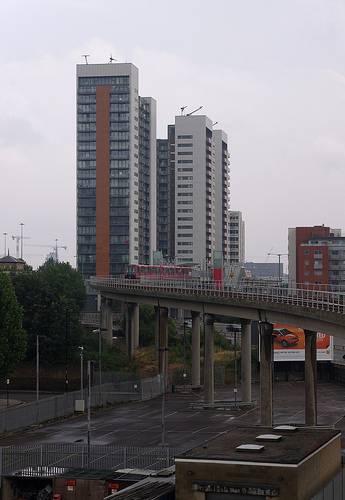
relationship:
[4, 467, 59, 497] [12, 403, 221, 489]
tunnel underneath lot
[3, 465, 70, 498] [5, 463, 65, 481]
trash dumpster has lid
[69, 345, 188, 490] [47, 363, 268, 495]
street lamp in parking lot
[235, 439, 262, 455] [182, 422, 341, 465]
skylight in roof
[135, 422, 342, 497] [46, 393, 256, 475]
building with parking lot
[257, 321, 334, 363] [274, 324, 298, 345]
billard advertising car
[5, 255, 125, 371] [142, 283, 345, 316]
trees beside railway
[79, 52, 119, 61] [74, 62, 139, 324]
antenna on top of building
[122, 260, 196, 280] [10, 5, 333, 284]
train is in the background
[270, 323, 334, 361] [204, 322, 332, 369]
billard in the background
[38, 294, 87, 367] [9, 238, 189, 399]
trees are in the background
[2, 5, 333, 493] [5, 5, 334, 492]
photo was taken in the daytime